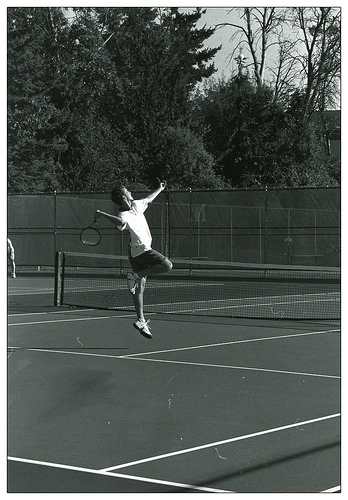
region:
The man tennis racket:
[78, 217, 102, 247]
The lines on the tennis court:
[124, 311, 335, 355]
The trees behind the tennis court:
[13, 95, 339, 180]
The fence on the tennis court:
[18, 196, 337, 269]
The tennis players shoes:
[124, 270, 152, 341]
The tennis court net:
[54, 248, 344, 320]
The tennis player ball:
[157, 177, 165, 187]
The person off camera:
[7, 238, 16, 285]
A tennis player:
[79, 181, 184, 338]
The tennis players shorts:
[130, 248, 163, 270]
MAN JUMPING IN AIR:
[66, 172, 213, 356]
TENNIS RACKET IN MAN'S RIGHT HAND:
[61, 204, 123, 255]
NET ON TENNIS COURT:
[47, 237, 334, 328]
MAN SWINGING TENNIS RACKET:
[62, 177, 207, 257]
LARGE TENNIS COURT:
[22, 260, 324, 477]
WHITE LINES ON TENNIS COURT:
[153, 316, 339, 452]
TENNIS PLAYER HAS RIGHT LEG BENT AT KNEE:
[115, 243, 199, 296]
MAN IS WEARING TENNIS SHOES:
[112, 261, 169, 346]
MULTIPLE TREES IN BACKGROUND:
[14, 5, 334, 189]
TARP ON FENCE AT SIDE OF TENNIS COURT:
[11, 192, 166, 278]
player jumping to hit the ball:
[74, 173, 182, 339]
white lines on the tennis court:
[5, 308, 340, 499]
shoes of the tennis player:
[123, 268, 152, 338]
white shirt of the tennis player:
[112, 194, 156, 253]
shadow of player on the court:
[38, 336, 128, 356]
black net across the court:
[55, 248, 342, 319]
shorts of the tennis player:
[124, 251, 171, 271]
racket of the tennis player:
[75, 217, 105, 250]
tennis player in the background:
[7, 237, 31, 280]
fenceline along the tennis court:
[12, 188, 343, 280]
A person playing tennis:
[58, 168, 196, 340]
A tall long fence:
[175, 177, 333, 275]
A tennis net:
[180, 245, 293, 327]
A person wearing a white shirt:
[113, 199, 165, 256]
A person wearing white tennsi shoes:
[129, 317, 160, 341]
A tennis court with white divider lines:
[101, 343, 283, 451]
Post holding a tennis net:
[39, 250, 75, 313]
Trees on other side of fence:
[24, 27, 301, 166]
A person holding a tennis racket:
[70, 206, 110, 249]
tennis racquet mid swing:
[81, 208, 104, 247]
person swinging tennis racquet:
[76, 209, 104, 248]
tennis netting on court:
[49, 247, 347, 325]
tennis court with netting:
[8, 282, 345, 496]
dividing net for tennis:
[54, 246, 337, 328]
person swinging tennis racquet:
[74, 177, 180, 335]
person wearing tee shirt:
[112, 198, 155, 254]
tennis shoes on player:
[131, 313, 155, 336]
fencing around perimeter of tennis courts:
[11, 189, 342, 288]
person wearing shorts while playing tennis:
[129, 249, 172, 272]